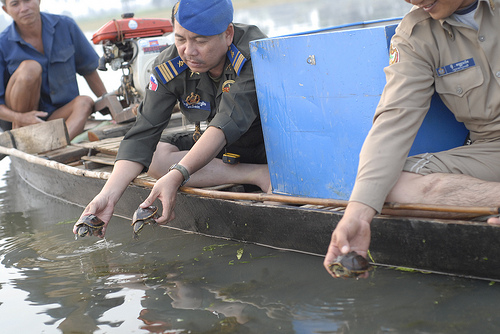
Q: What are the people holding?
A: Turtles.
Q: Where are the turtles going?
A: In the water.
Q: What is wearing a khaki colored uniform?
A: The man.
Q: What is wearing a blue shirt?
A: The man.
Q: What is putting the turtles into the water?
A: The men.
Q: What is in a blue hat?
A: A soldier.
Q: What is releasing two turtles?
A: A soldier.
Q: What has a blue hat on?
A: The man.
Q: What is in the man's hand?
A: Turtle.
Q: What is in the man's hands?
A: Two turtles.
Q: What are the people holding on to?
A: Turtles.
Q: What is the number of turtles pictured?
A: 3.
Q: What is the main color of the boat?
A: Black.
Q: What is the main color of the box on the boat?
A: Blue.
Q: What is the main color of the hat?
A: Blue.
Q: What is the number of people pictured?
A: 3.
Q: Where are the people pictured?
A: On a boat.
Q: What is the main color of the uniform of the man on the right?
A: Tan.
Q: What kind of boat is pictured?
A: Old boat.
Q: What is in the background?
A: Dirty murky water.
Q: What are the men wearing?
A: Uniforms.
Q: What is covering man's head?
A: Blue beret.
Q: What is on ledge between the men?
A: Large blue box.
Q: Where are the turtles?
A: In men's hands.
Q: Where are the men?
A: On boat.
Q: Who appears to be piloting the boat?
A: Man wearing blue shirt.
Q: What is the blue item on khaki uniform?
A: Name tag.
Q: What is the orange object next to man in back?
A: Engine.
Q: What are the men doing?
A: Releasing turtles into water.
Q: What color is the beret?
A: Blue.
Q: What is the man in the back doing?
A: Steering the boat.